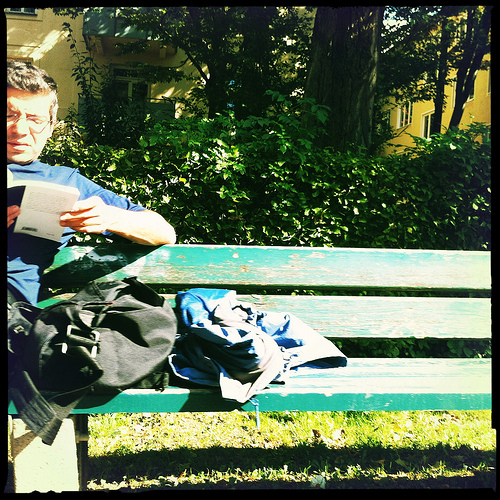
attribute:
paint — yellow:
[443, 56, 496, 131]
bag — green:
[0, 277, 180, 394]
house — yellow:
[365, 0, 496, 158]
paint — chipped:
[191, 243, 251, 274]